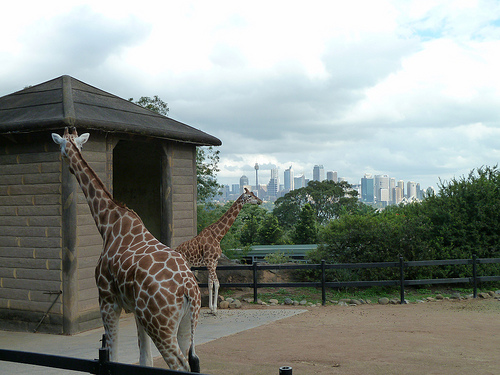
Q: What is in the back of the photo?
A: Skyline.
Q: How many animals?
A: Two.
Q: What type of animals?
A: Giraffes.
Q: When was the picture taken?
A: Cloudy day.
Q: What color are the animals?
A: Tan and white.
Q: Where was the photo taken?
A: Zoo.